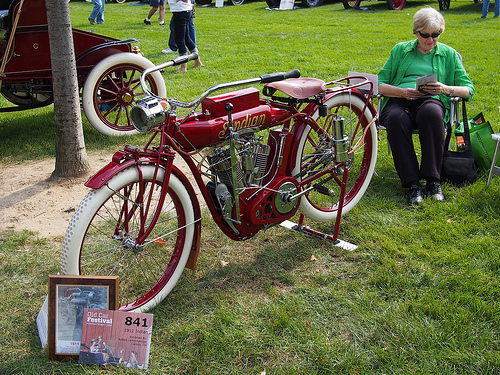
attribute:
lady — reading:
[380, 9, 477, 196]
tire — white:
[64, 159, 198, 326]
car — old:
[1, 4, 169, 135]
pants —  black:
[379, 101, 459, 203]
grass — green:
[2, 0, 499, 373]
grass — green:
[347, 221, 491, 326]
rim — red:
[299, 100, 373, 212]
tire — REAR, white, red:
[60, 164, 195, 311]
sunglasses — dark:
[409, 27, 441, 41]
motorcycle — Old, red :
[56, 51, 382, 324]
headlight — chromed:
[128, 94, 165, 132]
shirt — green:
[375, 39, 474, 121]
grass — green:
[226, 16, 363, 61]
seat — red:
[255, 64, 335, 102]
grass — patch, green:
[217, 303, 301, 374]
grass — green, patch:
[209, 293, 244, 339]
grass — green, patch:
[305, 339, 374, 371]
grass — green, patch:
[259, 280, 282, 302]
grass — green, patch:
[278, 272, 295, 286]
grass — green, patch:
[6, 232, 27, 247]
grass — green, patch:
[414, 226, 475, 301]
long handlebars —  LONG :
[123, 45, 325, 138]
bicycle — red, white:
[86, 61, 409, 302]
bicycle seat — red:
[264, 77, 329, 111]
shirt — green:
[363, 30, 478, 106]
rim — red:
[81, 175, 187, 311]